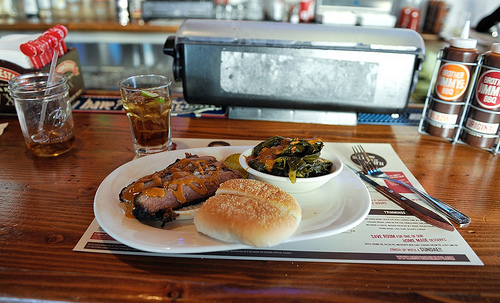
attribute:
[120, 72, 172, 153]
glass — part filled, full, shiny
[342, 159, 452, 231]
knife — silver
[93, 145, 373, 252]
plate — oblong, white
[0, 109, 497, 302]
table — brown, wooden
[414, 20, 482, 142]
bbq sauce bottle — selection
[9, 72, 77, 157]
jar — almost empty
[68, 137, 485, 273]
table mat — paper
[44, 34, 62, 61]
spoon — red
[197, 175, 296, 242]
bread — seeded, bun top, snack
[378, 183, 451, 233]
handle — wooden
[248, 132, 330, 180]
vegetable — green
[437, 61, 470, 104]
label — round, orange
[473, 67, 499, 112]
label — red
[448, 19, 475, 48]
top — white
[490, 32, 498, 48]
top — pointed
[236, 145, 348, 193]
bowl — small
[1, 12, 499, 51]
shelf — in background